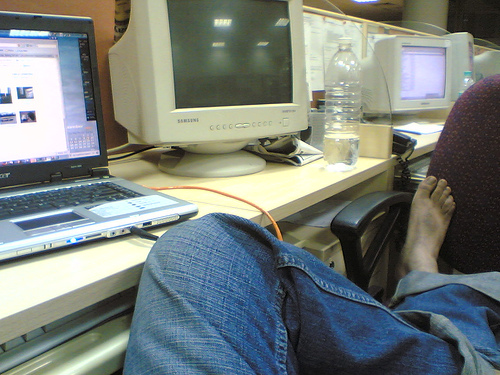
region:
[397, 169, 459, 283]
Barefoot on chair.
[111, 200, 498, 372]
blue jeans on person.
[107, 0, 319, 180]
White computer monitor on desk.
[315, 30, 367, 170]
Water bottle on the desk.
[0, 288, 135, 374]
White keyboard on keyboard shelf.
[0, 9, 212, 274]
laptop on the desk.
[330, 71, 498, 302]
chair in front of the desk.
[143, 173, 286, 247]
Orange cable on the desk.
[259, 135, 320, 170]
Paper on the desk.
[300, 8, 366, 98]
Papers on the wall.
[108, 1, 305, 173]
a gray computer monitor on a desk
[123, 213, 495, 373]
a person wearing blue jeans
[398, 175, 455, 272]
a person barefoot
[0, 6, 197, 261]
a laptop on a desk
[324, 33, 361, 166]
a bottle of water on a desk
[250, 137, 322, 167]
folded papers next to a computer monitor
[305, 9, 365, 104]
papers tacked on a cork board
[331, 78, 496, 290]
a red swiveling chair with black handles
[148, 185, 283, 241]
an orange wire on a desk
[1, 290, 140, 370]
edge of a silver keyboard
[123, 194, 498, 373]
pair of blue jeans with rolled up cuffs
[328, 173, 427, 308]
black handle of chair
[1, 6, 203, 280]
open silver and black laptop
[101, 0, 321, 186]
tan computer monitor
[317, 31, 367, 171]
clear plastic bottle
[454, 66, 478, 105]
clear plastic bottle with green cap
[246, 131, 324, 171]
newspaper folded in half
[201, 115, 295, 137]
buttons on front of monitor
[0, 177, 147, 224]
black keys on keypad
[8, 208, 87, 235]
balck trackpad on laptop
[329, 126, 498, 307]
a foot on a chair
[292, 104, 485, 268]
a foot on a computer chain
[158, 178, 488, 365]
a person wearing jeans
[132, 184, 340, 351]
a person wearing blue jeans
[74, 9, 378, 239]
an old computer monitor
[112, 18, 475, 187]
an old computer monitor turned off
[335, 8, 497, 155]
old computer monitor turned on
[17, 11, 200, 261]
a laptop on the desk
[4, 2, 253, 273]
an open laptop turned on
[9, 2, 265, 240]
an open laptop on the table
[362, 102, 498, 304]
a barefoot propped up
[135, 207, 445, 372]
a pair of denim pants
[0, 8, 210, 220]
a black laptop computer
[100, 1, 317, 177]
an old white desktop computer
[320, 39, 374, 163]
a partially filled water bottle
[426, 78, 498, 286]
the red fabric of an office chair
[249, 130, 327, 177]
a folded piece of paper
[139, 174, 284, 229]
a yellow colored computer cable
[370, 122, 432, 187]
a black land line phone with a cord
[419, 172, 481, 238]
a persons dirty toes